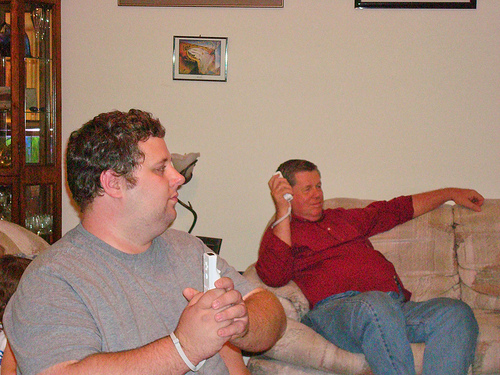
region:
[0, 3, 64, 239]
a curio cabinet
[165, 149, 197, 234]
an off table lamp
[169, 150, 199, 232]
a lamp shaped like a flower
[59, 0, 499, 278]
a white painted wall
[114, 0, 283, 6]
a brown wood frame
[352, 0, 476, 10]
a black wood frame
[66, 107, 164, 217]
brown curly hair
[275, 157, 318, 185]
man's short brown hair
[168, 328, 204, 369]
a white wrist band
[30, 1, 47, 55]
a long stemmed glass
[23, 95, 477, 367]
two men playing video games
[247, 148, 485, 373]
man with blue jeans and a red shirt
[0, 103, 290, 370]
man with a gray tee shirt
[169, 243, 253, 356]
two hands holding a video game controller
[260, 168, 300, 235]
one hand holding a video game controller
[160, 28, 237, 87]
framed art work on wall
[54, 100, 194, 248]
man's head with dark brown hair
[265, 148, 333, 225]
man's head with dark brown hair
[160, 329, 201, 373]
plastic bracelet on man's wrist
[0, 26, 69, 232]
wood and glass display case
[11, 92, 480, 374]
two men playing Wii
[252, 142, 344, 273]
a man holding a Wii remote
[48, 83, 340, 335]
two men holding Wii controllers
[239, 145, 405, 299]
a man wearing a red shirt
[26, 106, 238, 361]
a man wearing a gray shirt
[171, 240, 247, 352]
two hands holding a Wii controller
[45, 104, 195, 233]
a man with brown hair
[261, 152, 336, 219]
a man with short hair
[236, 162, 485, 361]
a man sitting on a couch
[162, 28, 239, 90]
a picture on the wall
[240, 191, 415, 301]
man's shirt is red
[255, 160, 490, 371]
man holding a game controller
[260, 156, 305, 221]
the controller is white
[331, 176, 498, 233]
man's arm on couch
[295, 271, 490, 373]
man is wearing blue jeans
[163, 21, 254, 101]
picture framed on wall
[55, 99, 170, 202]
man's hair is curly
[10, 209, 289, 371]
man's shirt is gray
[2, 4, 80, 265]
shelf behind the men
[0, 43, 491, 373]
men are playing a game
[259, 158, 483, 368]
a man playing a video game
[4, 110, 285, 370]
a man playing a video game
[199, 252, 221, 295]
a Wii video game controller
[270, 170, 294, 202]
a Wii video game controller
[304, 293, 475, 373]
a pair of blue jeans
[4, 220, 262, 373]
a man's grey t-shirt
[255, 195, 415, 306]
a man's red shirt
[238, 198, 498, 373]
a light brown patterned couch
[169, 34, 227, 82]
a framed art print